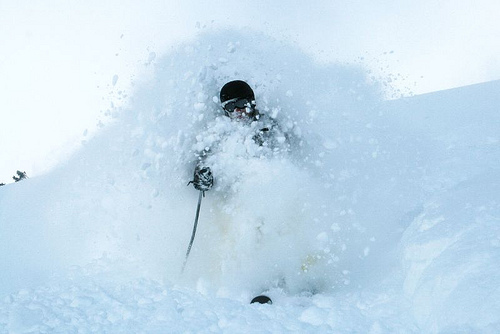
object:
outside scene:
[0, 0, 500, 333]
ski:
[252, 294, 271, 304]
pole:
[179, 165, 211, 276]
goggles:
[221, 99, 249, 112]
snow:
[0, 0, 499, 333]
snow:
[223, 96, 254, 122]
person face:
[225, 97, 254, 124]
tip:
[250, 294, 273, 305]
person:
[193, 78, 290, 305]